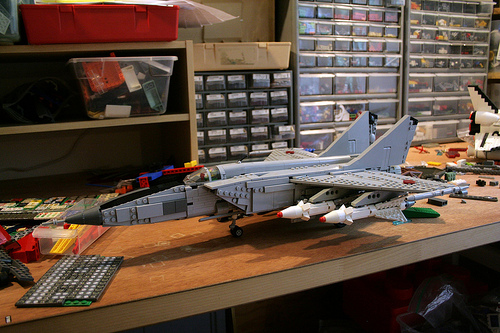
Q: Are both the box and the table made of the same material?
A: No, the box is made of plastic and the table is made of wood.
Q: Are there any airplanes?
A: Yes, there is an airplane.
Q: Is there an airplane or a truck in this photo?
A: Yes, there is an airplane.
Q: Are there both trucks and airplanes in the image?
A: No, there is an airplane but no trucks.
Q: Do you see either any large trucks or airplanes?
A: Yes, there is a large airplane.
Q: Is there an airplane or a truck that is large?
A: Yes, the airplane is large.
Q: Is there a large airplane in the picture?
A: Yes, there is a large airplane.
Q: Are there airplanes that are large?
A: Yes, there is an airplane that is large.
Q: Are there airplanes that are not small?
A: Yes, there is a large airplane.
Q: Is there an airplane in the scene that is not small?
A: Yes, there is a large airplane.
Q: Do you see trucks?
A: No, there are no trucks.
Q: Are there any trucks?
A: No, there are no trucks.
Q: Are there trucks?
A: No, there are no trucks.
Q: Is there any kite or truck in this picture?
A: No, there are no trucks or kites.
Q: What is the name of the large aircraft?
A: The aircraft is an airplane.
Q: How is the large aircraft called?
A: The aircraft is an airplane.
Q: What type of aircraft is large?
A: The aircraft is an airplane.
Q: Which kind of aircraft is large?
A: The aircraft is an airplane.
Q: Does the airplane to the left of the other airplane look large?
A: Yes, the airplane is large.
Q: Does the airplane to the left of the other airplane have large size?
A: Yes, the airplane is large.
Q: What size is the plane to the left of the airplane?
A: The plane is large.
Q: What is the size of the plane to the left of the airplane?
A: The plane is large.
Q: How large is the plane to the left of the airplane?
A: The plane is large.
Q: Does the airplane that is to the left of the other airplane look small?
A: No, the plane is large.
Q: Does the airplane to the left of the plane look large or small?
A: The plane is large.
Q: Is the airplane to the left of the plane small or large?
A: The plane is large.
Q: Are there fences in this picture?
A: No, there are no fences.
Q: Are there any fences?
A: No, there are no fences.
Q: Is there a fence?
A: No, there are no fences.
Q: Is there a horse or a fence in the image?
A: No, there are no fences or horses.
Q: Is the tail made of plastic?
A: Yes, the tail is made of plastic.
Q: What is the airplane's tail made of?
A: The tail is made of plastic.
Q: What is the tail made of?
A: The tail is made of plastic.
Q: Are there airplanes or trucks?
A: Yes, there is an airplane.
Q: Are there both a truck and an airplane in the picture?
A: No, there is an airplane but no trucks.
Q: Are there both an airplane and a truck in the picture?
A: No, there is an airplane but no trucks.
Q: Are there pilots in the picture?
A: No, there are no pilots.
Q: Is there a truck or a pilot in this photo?
A: No, there are no pilots or trucks.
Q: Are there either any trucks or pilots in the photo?
A: No, there are no pilots or trucks.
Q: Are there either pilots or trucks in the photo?
A: No, there are no pilots or trucks.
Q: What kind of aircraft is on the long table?
A: The aircraft is an airplane.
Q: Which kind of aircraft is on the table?
A: The aircraft is an airplane.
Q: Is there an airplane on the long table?
A: Yes, there is an airplane on the table.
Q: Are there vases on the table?
A: No, there is an airplane on the table.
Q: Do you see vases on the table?
A: No, there is an airplane on the table.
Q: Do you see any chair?
A: No, there are no chairs.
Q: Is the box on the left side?
A: Yes, the box is on the left of the image.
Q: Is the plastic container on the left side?
A: Yes, the box is on the left of the image.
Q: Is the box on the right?
A: No, the box is on the left of the image.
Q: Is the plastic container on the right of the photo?
A: No, the box is on the left of the image.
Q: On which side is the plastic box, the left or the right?
A: The box is on the left of the image.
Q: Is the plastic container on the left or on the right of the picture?
A: The box is on the left of the image.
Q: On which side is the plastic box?
A: The box is on the left of the image.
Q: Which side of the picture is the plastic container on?
A: The box is on the left of the image.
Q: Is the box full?
A: Yes, the box is full.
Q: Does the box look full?
A: Yes, the box is full.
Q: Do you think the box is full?
A: Yes, the box is full.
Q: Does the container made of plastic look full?
A: Yes, the box is full.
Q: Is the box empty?
A: No, the box is full.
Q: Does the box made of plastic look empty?
A: No, the box is full.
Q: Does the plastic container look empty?
A: No, the box is full.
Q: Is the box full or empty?
A: The box is full.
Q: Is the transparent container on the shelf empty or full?
A: The box is full.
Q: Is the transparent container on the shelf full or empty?
A: The box is full.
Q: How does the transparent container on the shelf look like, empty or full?
A: The box is full.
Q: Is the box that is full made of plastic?
A: Yes, the box is made of plastic.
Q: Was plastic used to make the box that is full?
A: Yes, the box is made of plastic.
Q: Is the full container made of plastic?
A: Yes, the box is made of plastic.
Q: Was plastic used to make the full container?
A: Yes, the box is made of plastic.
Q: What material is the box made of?
A: The box is made of plastic.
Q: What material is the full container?
A: The box is made of plastic.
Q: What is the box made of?
A: The box is made of plastic.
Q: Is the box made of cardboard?
A: No, the box is made of plastic.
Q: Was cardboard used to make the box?
A: No, the box is made of plastic.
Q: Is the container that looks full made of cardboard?
A: No, the box is made of plastic.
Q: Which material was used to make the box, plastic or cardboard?
A: The box is made of plastic.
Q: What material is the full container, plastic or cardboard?
A: The box is made of plastic.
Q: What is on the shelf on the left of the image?
A: The box is on the shelf.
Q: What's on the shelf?
A: The box is on the shelf.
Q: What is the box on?
A: The box is on the shelf.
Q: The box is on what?
A: The box is on the shelf.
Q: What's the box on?
A: The box is on the shelf.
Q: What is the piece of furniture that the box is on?
A: The piece of furniture is a shelf.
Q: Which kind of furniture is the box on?
A: The box is on the shelf.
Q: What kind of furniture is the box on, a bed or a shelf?
A: The box is on a shelf.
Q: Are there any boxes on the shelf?
A: Yes, there is a box on the shelf.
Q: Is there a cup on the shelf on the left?
A: No, there is a box on the shelf.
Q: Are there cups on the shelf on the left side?
A: No, there is a box on the shelf.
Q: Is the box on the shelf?
A: Yes, the box is on the shelf.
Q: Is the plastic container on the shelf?
A: Yes, the box is on the shelf.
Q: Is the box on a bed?
A: No, the box is on the shelf.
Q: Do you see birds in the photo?
A: No, there are no birds.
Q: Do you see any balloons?
A: No, there are no balloons.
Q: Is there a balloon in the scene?
A: No, there are no balloons.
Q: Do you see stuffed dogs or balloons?
A: No, there are no balloons or stuffed dogs.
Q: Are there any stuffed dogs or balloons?
A: No, there are no balloons or stuffed dogs.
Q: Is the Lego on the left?
A: Yes, the Lego is on the left of the image.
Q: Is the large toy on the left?
A: Yes, the Lego is on the left of the image.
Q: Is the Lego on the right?
A: No, the Lego is on the left of the image.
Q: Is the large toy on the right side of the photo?
A: No, the Lego is on the left of the image.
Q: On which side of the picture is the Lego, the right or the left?
A: The Lego is on the left of the image.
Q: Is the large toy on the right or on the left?
A: The Lego is on the left of the image.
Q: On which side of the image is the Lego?
A: The Lego is on the left of the image.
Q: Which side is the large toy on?
A: The Lego is on the left of the image.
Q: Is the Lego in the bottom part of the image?
A: Yes, the Lego is in the bottom of the image.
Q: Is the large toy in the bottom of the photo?
A: Yes, the Lego is in the bottom of the image.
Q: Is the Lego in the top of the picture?
A: No, the Lego is in the bottom of the image.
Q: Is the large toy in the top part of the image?
A: No, the Lego is in the bottom of the image.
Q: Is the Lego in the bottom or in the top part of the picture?
A: The Lego is in the bottom of the image.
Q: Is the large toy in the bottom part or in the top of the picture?
A: The Lego is in the bottom of the image.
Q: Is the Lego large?
A: Yes, the Lego is large.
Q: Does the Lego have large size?
A: Yes, the Lego is large.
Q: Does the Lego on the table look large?
A: Yes, the Lego is large.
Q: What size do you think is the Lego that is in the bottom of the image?
A: The Lego is large.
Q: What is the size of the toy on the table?
A: The Lego is large.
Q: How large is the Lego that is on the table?
A: The Lego is large.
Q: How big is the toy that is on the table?
A: The Lego is large.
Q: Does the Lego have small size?
A: No, the Lego is large.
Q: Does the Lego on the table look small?
A: No, the Lego is large.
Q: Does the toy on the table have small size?
A: No, the Lego is large.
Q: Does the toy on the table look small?
A: No, the Lego is large.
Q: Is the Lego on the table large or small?
A: The Lego is large.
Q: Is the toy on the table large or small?
A: The Lego is large.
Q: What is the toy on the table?
A: The toy is a Lego.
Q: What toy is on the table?
A: The toy is a Lego.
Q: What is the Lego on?
A: The Lego is on the table.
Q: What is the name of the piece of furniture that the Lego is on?
A: The piece of furniture is a table.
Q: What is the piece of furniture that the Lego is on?
A: The piece of furniture is a table.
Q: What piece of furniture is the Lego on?
A: The Lego is on the table.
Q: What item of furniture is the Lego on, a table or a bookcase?
A: The Lego is on a table.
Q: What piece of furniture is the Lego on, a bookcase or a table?
A: The Lego is on a table.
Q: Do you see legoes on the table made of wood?
A: Yes, there is a Lego on the table.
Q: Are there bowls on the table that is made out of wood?
A: No, there is a Lego on the table.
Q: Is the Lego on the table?
A: Yes, the Lego is on the table.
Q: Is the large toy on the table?
A: Yes, the Lego is on the table.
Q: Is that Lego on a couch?
A: No, the Lego is on the table.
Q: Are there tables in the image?
A: Yes, there is a table.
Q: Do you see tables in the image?
A: Yes, there is a table.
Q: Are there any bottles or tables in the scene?
A: Yes, there is a table.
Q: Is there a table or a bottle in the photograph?
A: Yes, there is a table.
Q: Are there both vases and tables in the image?
A: No, there is a table but no vases.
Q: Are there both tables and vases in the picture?
A: No, there is a table but no vases.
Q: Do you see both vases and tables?
A: No, there is a table but no vases.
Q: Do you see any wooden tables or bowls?
A: Yes, there is a wood table.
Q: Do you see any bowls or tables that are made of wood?
A: Yes, the table is made of wood.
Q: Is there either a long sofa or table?
A: Yes, there is a long table.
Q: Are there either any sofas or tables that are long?
A: Yes, the table is long.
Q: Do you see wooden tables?
A: Yes, there is a wood table.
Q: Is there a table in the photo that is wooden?
A: Yes, there is a table that is wooden.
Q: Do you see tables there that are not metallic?
A: Yes, there is a wooden table.